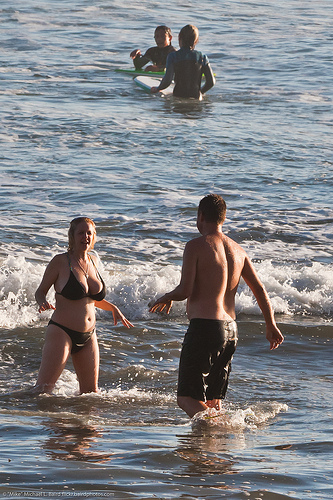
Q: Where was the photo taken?
A: At a beach.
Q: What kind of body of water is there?
A: An ocean.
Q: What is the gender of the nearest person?
A: Male.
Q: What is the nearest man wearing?
A: Shorts.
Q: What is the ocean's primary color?
A: Blue.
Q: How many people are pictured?
A: 4.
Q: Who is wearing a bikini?
A: Woman.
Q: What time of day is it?
A: Daytime.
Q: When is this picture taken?
A: At the beach.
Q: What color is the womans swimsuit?
A: Black.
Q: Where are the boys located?
A: In the back.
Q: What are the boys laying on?
A: Surfboard.